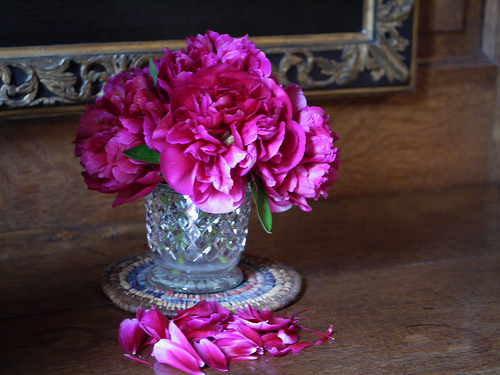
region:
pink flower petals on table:
[115, 296, 342, 373]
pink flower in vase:
[248, 83, 305, 202]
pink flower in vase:
[192, 65, 274, 127]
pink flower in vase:
[161, 118, 256, 225]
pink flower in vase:
[83, 108, 151, 200]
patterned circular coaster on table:
[100, 248, 305, 314]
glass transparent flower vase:
[144, 179, 254, 287]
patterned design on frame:
[310, 0, 417, 98]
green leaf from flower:
[242, 163, 282, 236]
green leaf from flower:
[123, 142, 162, 169]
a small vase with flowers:
[127, 181, 252, 302]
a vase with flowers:
[70, 15, 340, 295]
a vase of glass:
[136, 172, 257, 292]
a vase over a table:
[0, 137, 496, 357]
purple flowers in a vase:
[56, 22, 351, 292]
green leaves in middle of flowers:
[113, 131, 168, 186]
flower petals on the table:
[96, 291, 337, 371]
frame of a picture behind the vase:
[7, 1, 432, 142]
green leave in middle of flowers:
[133, 45, 173, 101]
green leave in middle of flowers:
[245, 166, 286, 237]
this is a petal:
[198, 83, 217, 98]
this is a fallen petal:
[147, 327, 212, 374]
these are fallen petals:
[108, 281, 328, 373]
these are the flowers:
[78, 23, 354, 226]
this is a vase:
[93, 154, 305, 361]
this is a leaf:
[238, 164, 288, 251]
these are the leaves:
[112, 53, 322, 255]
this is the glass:
[152, 199, 187, 256]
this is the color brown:
[466, 313, 497, 338]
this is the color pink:
[178, 358, 186, 361]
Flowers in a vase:
[106, 50, 229, 180]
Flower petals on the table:
[102, 287, 316, 362]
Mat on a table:
[110, 245, 321, 340]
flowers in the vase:
[108, 60, 280, 180]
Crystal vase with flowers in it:
[126, 167, 213, 268]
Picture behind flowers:
[76, 30, 460, 103]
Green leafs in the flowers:
[123, 129, 283, 221]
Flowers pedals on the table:
[94, 298, 213, 343]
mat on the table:
[100, 254, 306, 324]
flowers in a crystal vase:
[72, 62, 312, 229]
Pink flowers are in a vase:
[73, 37, 365, 257]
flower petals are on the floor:
[92, 308, 361, 370]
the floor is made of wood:
[288, 243, 496, 344]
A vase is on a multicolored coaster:
[82, 245, 485, 351]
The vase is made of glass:
[122, 160, 352, 357]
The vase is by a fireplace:
[2, 26, 485, 181]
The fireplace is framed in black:
[36, 10, 495, 80]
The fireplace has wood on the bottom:
[271, 26, 463, 139]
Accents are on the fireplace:
[276, 23, 446, 134]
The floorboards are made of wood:
[14, 142, 156, 353]